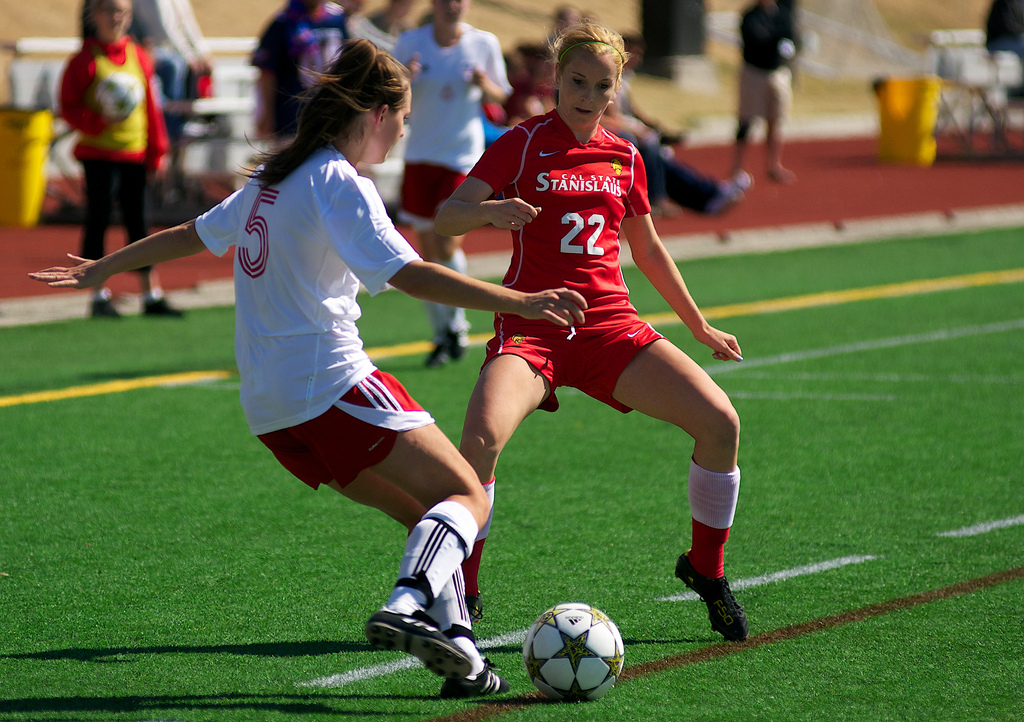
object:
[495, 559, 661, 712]
ball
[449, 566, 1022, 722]
line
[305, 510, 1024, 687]
line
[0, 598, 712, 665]
shadow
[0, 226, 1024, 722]
greengrass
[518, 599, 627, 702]
design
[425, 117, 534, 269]
arm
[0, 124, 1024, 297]
redground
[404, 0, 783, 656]
female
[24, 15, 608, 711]
female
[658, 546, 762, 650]
shoe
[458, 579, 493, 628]
shoe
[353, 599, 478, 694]
shoe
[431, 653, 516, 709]
shoe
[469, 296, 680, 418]
shorts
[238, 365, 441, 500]
shorts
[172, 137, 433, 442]
jersey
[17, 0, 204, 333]
person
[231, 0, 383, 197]
person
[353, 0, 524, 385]
person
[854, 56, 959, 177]
bin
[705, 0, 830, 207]
person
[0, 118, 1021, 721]
ground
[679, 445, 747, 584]
sock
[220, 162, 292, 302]
number